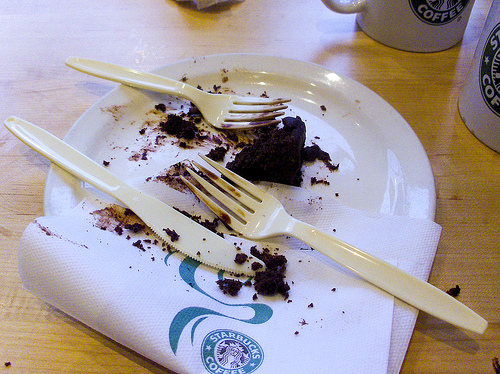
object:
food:
[143, 93, 343, 298]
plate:
[42, 54, 435, 348]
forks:
[63, 54, 296, 129]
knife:
[4, 116, 272, 278]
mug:
[457, 1, 500, 152]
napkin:
[13, 176, 442, 373]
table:
[2, 2, 497, 372]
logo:
[195, 328, 266, 373]